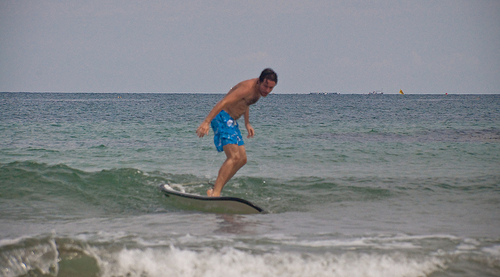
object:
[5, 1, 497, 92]
sky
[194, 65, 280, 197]
man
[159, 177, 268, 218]
surfboard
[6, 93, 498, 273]
water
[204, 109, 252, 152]
shorts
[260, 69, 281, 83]
hair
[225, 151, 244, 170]
knees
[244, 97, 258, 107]
chesthair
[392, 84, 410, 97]
object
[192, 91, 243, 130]
arm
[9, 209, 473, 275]
wave